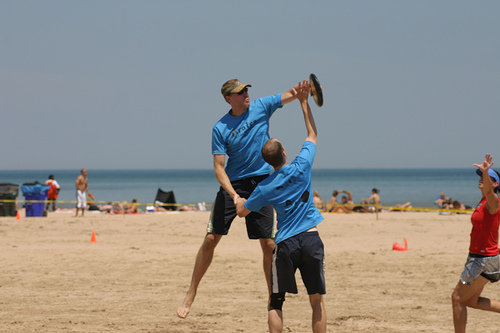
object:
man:
[176, 78, 322, 318]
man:
[235, 80, 326, 332]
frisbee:
[309, 73, 324, 107]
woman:
[362, 188, 382, 211]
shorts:
[460, 251, 500, 286]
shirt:
[469, 196, 500, 256]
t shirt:
[212, 93, 283, 181]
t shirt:
[244, 140, 324, 244]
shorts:
[207, 175, 277, 239]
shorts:
[271, 231, 326, 295]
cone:
[392, 238, 408, 252]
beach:
[1, 208, 499, 332]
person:
[44, 174, 60, 212]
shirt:
[45, 179, 60, 199]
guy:
[74, 168, 94, 218]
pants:
[76, 189, 88, 209]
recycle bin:
[20, 181, 52, 217]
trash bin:
[0, 183, 20, 217]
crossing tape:
[0, 197, 477, 216]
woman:
[451, 153, 500, 333]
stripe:
[272, 243, 279, 294]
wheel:
[42, 210, 47, 217]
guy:
[337, 189, 375, 212]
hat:
[221, 79, 252, 98]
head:
[221, 79, 252, 109]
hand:
[291, 79, 312, 101]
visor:
[475, 167, 499, 183]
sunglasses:
[228, 87, 249, 97]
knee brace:
[268, 291, 286, 312]